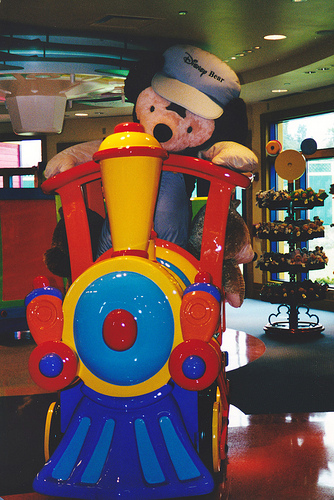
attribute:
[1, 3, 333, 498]
scene — of building interior, of disney store, including front desk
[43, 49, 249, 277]
toy — mickey mouse, large stuffed, wearing hat, wearing coveralls, wearing a hat, like teddy bear, a doll, stuffed mickey mouse, disney toy, like bear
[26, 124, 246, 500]
toy train — red yellow, blue, large, large riding train, blue red, train engine, yellow, looking like plastic, disney train, plastic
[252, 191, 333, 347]
rack of toys — 4 tiers, tall tiered item, tiered metal, metal structure, tiered, holding animals, disney toys, stuffed toys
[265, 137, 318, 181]
mickey mouse head — shaped like ears, metal, mouse-head shaped, famous logo, mickey mouse topper, facing out window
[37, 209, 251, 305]
bear passengers — total of 3, stuffed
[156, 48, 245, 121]
hat — grey, black, looking blue, tan, conductes hat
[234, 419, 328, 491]
floor — shiny, red, tiled, brown, wooden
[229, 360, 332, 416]
rug — close to floor tile, black carpet, black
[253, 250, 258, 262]
nose — black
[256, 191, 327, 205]
stuffed animals — resembling flowers, on tiers of rack, on rack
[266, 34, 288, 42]
light — on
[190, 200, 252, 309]
bear — looking out window, sitting on train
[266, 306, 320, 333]
design on base — mickey mouse shaped, shaped like mickey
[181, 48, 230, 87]
disney bear — written on hat